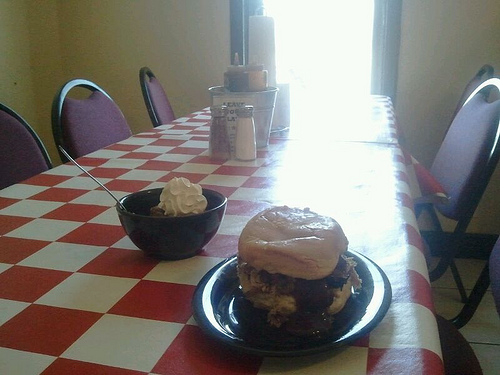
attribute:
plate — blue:
[190, 324, 347, 343]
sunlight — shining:
[284, 77, 393, 267]